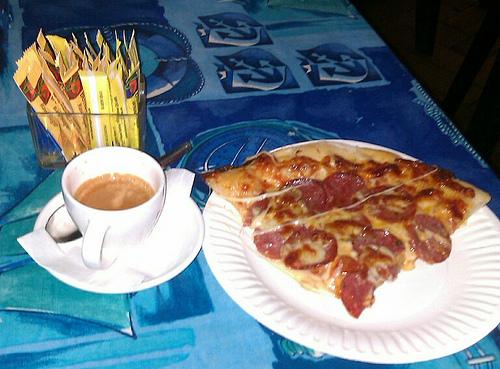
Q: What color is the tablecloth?
A: Blue.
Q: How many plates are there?
A: Two.